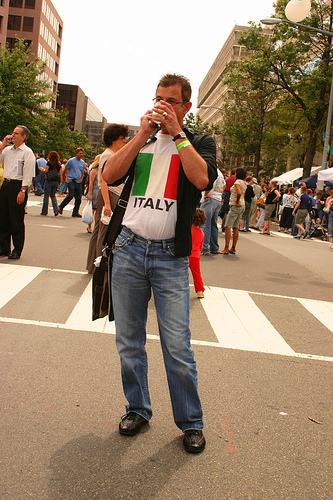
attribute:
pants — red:
[190, 257, 205, 291]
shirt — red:
[189, 226, 203, 256]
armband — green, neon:
[174, 137, 192, 154]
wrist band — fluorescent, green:
[172, 140, 194, 151]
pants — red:
[186, 252, 211, 294]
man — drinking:
[101, 71, 210, 453]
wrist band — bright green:
[175, 139, 190, 149]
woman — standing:
[217, 166, 246, 255]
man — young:
[89, 73, 231, 453]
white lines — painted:
[0, 262, 332, 363]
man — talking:
[2, 120, 37, 265]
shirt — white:
[118, 128, 186, 250]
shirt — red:
[196, 228, 210, 247]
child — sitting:
[312, 218, 326, 231]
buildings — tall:
[187, 11, 331, 187]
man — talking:
[0, 124, 35, 259]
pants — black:
[0, 176, 28, 260]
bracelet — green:
[175, 139, 191, 150]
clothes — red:
[189, 226, 204, 292]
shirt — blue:
[65, 158, 86, 184]